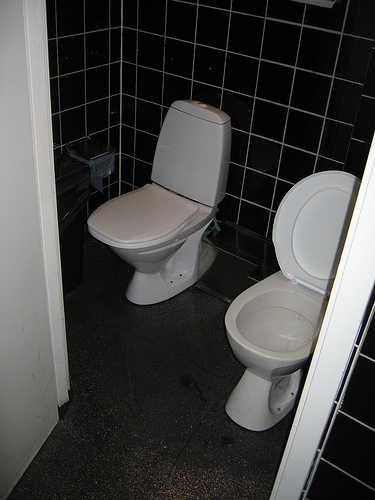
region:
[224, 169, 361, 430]
A toilet in the bathroom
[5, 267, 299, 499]
The ground beneath the toilets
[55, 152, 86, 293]
A trash can in the bathroom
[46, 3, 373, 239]
The wall of the bathroom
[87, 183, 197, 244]
The lid of the toilet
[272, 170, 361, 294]
The seat of the toilet is up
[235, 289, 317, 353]
The bowl of the toilet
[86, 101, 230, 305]
A toilet near the trash can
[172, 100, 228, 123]
The tank of the toilet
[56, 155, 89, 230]
A trash bag in the trash can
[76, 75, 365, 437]
two toilets right next to each other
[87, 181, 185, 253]
toilet lid is down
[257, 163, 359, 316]
toilet seat is up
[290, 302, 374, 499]
black tile on the wall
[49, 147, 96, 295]
trash can pushed up against the wall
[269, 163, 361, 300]
toilet lid is up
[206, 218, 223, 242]
pipes behind the toilet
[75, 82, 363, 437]
two white porcelain toilets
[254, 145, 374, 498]
corner of the wall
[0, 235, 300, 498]
the floor is dark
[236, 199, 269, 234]
black tile on wall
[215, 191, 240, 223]
black tile on wall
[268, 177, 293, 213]
black tile on wall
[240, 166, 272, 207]
black tile on wall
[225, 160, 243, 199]
black tile on wall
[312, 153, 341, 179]
black tile on wall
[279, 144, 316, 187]
black tile on wall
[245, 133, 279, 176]
black tile on wall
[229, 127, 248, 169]
black tile on wall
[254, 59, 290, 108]
black tile on wall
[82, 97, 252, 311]
a white toilet in a bathroom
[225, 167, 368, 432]
a white toilet in a bathroom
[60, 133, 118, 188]
a toilet paper dispenser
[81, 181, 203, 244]
a white toilet lid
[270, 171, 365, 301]
a white toilet lid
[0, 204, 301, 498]
a bathroom with a black floor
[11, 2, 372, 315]
a bathroom with a black tile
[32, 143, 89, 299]
a trash can in a bathroom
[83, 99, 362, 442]
two bathrooms in a toilet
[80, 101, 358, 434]
two bathrooms next to each other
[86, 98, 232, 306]
a white porcelain toilet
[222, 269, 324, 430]
a white porcelain toilet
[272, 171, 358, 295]
a white plastic toilet seat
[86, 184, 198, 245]
a white plastic toilet seat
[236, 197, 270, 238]
a black bathroom wall tile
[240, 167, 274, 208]
a black bathroom wall tile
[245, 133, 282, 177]
a black bathroom wall tile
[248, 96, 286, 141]
a black bathroom wall tile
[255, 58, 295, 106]
a black bathroom wall tile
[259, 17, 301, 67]
a black bathroom wall tile